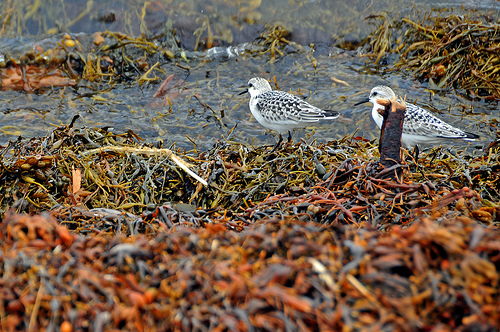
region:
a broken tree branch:
[376, 94, 395, 176]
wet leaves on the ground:
[129, 237, 311, 292]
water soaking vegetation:
[125, 77, 226, 132]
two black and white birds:
[236, 68, 456, 145]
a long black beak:
[241, 77, 247, 98]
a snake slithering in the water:
[191, 39, 266, 59]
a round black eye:
[246, 79, 258, 92]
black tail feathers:
[469, 124, 484, 144]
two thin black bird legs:
[273, 131, 288, 150]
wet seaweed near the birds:
[74, 141, 244, 196]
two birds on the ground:
[204, 56, 436, 154]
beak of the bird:
[343, 88, 374, 128]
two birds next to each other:
[202, 77, 422, 164]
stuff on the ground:
[201, 163, 278, 219]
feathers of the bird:
[265, 96, 303, 129]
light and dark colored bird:
[191, 81, 326, 182]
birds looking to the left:
[231, 56, 447, 171]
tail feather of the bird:
[448, 124, 488, 159]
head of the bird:
[351, 78, 393, 118]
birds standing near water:
[213, 70, 441, 157]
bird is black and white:
[240, 79, 340, 156]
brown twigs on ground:
[85, 123, 275, 220]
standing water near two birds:
[114, 58, 241, 150]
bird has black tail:
[284, 92, 360, 142]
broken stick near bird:
[378, 81, 399, 148]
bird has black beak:
[340, 90, 369, 113]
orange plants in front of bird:
[159, 211, 431, 319]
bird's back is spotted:
[403, 95, 425, 134]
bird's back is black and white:
[385, 97, 424, 145]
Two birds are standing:
[217, 44, 495, 191]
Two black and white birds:
[231, 72, 493, 152]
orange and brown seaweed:
[14, 198, 476, 330]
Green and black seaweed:
[21, 114, 471, 209]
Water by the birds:
[7, 50, 496, 159]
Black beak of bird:
[349, 93, 374, 115]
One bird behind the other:
[224, 58, 497, 145]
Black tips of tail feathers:
[321, 101, 341, 126]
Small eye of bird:
[370, 88, 378, 99]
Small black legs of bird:
[268, 127, 299, 150]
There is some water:
[22, 85, 133, 125]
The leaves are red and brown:
[22, 260, 206, 325]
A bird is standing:
[241, 73, 333, 155]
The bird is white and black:
[350, 80, 478, 163]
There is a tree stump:
[378, 99, 404, 178]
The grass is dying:
[211, 151, 302, 196]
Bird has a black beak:
[348, 93, 370, 110]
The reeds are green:
[380, 11, 498, 61]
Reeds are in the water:
[125, 43, 240, 146]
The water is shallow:
[12, 75, 244, 145]